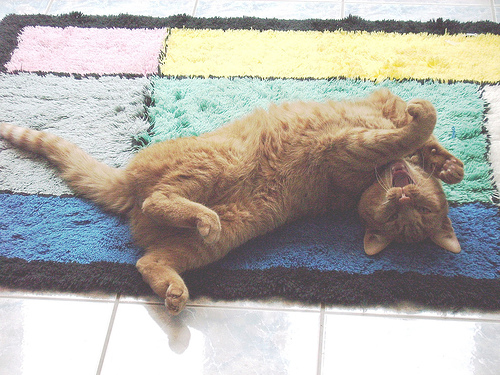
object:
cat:
[0, 91, 460, 316]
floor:
[0, 2, 496, 371]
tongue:
[393, 170, 409, 186]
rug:
[0, 14, 500, 310]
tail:
[0, 121, 126, 215]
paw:
[406, 98, 438, 122]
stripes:
[11, 127, 26, 144]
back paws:
[159, 278, 189, 314]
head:
[357, 161, 462, 256]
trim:
[0, 11, 170, 82]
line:
[93, 303, 116, 375]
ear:
[363, 228, 387, 257]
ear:
[431, 225, 463, 254]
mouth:
[388, 162, 410, 191]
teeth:
[402, 165, 405, 167]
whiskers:
[424, 165, 436, 184]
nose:
[399, 191, 410, 204]